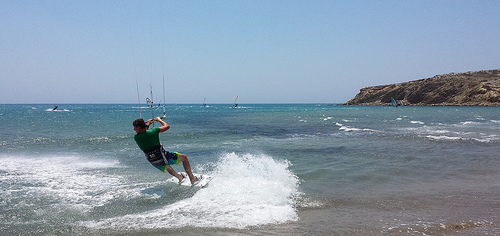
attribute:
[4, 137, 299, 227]
waves — bright, white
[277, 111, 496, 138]
waves — distant, cresting, ocean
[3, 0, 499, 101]
sky — hazy, light blue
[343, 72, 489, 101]
mountain — green, big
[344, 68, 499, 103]
point — rocky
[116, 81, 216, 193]
surfer — adult, white, male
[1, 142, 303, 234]
white waves — splashing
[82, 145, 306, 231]
wave — small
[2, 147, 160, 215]
wave — small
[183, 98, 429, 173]
water — calm, blue, ocean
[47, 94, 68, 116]
mountain — big, green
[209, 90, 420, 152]
water — turquoise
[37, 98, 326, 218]
surfer — wind, leaning, backwards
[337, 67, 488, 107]
mountain — big, green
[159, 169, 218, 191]
board — white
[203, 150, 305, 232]
wave top — splashing, white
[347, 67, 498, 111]
mountain — big, green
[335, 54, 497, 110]
mountain — green, big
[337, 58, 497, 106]
mountain — green, big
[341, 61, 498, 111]
cliff — brown, grey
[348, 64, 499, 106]
cliff — brown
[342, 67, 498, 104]
mountain — green, big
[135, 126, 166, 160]
shirt — green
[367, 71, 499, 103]
mountain — big, green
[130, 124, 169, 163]
shirt — green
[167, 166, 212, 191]
platform — white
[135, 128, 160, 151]
shirt — green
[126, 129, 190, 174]
shorts — black, green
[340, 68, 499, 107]
mountain — big, green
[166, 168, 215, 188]
board — white, wave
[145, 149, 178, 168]
swim trunks — multicolroed